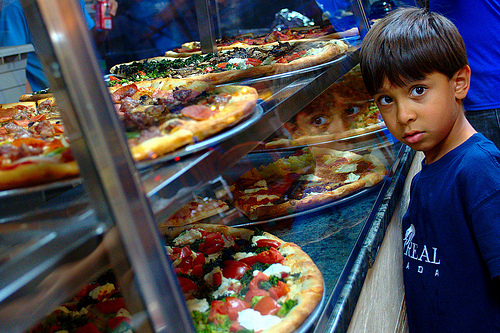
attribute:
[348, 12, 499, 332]
boy — not smiling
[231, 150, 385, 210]
pizza — cooked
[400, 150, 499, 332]
shirt — blue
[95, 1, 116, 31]
soda can — red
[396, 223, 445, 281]
logo — white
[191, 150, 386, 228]
tray — metal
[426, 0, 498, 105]
shirt — blue